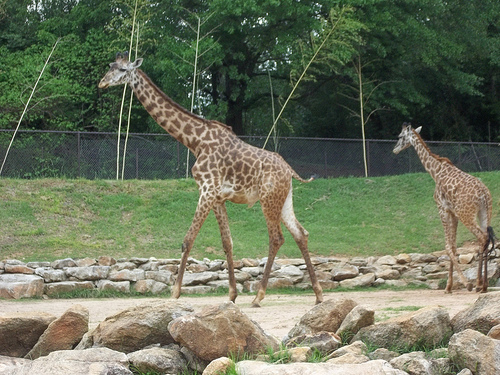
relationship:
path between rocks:
[2, 287, 487, 317] [1, 292, 498, 369]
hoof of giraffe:
[446, 279, 458, 296] [381, 111, 498, 291]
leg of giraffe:
[212, 208, 242, 305] [112, 65, 327, 314]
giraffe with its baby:
[95, 53, 324, 310] [391, 119, 494, 293]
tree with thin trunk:
[339, 47, 394, 178] [360, 121, 372, 178]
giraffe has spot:
[95, 53, 324, 310] [182, 120, 194, 136]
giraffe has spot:
[95, 53, 324, 310] [183, 135, 200, 150]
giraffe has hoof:
[95, 53, 324, 310] [249, 299, 262, 306]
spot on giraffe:
[134, 88, 142, 95] [95, 53, 324, 310]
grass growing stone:
[7, 197, 112, 227] [315, 255, 402, 289]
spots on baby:
[451, 183, 461, 194] [391, 119, 494, 292]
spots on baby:
[450, 176, 458, 186] [391, 119, 494, 292]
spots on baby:
[441, 178, 451, 186] [391, 119, 494, 292]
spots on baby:
[459, 187, 469, 192] [391, 119, 494, 292]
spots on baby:
[434, 163, 442, 174] [391, 119, 494, 292]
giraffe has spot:
[102, 62, 345, 284] [201, 123, 224, 153]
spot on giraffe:
[157, 93, 166, 106] [96, 51, 310, 267]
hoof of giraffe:
[252, 300, 262, 307] [95, 53, 324, 310]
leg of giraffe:
[178, 89, 318, 276] [81, 50, 356, 326]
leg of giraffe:
[280, 191, 325, 306] [95, 53, 324, 310]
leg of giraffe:
[148, 172, 233, 301] [46, 24, 339, 302]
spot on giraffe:
[230, 160, 245, 172] [95, 53, 324, 310]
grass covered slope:
[15, 154, 424, 271] [3, 166, 498, 266]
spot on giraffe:
[144, 102, 158, 112] [95, 53, 324, 310]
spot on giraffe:
[153, 82, 203, 147] [54, 46, 391, 323]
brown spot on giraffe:
[218, 145, 245, 160] [84, 53, 344, 362]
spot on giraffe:
[178, 137, 245, 182] [95, 53, 324, 310]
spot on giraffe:
[180, 120, 194, 137] [95, 53, 324, 310]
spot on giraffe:
[162, 109, 174, 124] [95, 53, 324, 310]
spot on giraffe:
[170, 114, 184, 124] [95, 53, 324, 310]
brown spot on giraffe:
[221, 167, 238, 187] [88, 36, 363, 301]